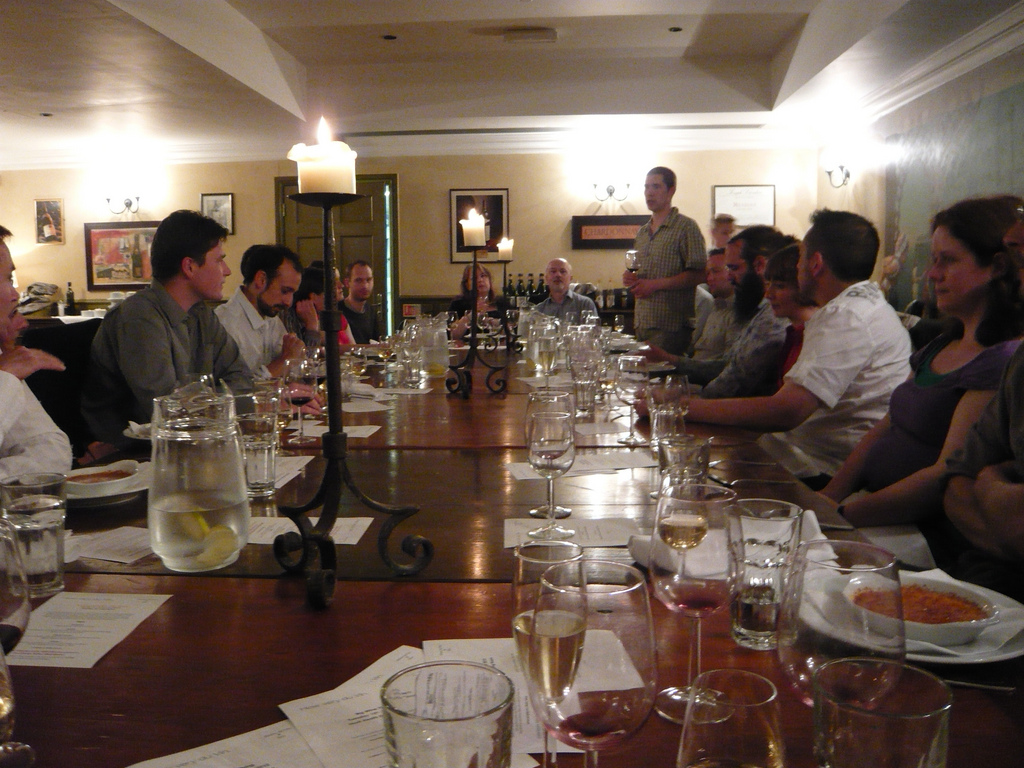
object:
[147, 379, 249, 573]
pitcher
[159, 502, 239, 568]
lemons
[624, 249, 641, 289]
beverage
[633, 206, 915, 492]
man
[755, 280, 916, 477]
shirt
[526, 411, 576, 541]
glass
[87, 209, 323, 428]
man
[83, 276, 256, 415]
shirt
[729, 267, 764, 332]
beard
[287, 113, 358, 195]
candle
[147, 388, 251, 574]
flask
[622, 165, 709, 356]
man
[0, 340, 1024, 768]
dinner table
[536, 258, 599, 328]
gentleman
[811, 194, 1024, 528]
woman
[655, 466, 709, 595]
glass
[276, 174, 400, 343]
door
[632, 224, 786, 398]
man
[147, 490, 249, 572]
water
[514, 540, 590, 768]
champagne flute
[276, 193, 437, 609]
candle holder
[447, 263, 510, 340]
woman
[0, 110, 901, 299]
wall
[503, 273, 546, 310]
wine bottles